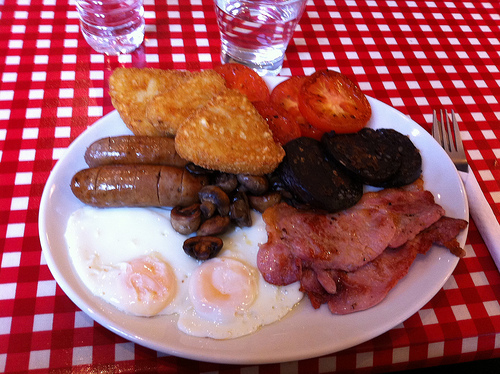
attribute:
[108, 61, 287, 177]
two has browns — brown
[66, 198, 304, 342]
two cooked eggs — over easy cooked, cooked soft, sunny side up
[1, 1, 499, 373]
tablecloth — checkered, red, white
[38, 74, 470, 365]
plate — white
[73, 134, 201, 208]
couple of sausages — short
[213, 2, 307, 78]
glass — made of glass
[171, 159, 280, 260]
mushrooms — cooked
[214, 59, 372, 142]
tomato slices — grilled, sliced, red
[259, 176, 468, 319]
few slices of ham — pieces, cooked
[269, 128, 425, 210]
food — burnt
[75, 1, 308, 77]
two plastic bottles — water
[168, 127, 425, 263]
two types of food — black